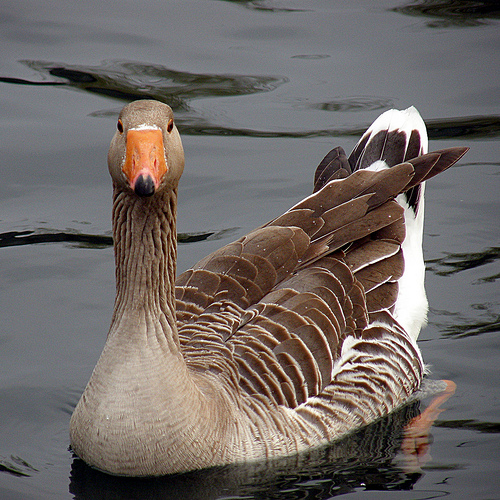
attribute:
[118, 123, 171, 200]
beak — orange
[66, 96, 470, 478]
bird — brown, white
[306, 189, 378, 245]
feather — brown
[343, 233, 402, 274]
feather — brown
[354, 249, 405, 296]
feather — brown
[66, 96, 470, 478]
duck —  brown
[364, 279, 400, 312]
feather — brown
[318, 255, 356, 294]
feather — brown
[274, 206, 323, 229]
feather — Brown,  duck's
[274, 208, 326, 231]
feather —  duck's,  Brown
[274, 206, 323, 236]
feather —  Brown,  duck's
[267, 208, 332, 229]
feather —  duck's,  Brown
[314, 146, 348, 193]
tail —  black,  duck's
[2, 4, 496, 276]
water —  very dark